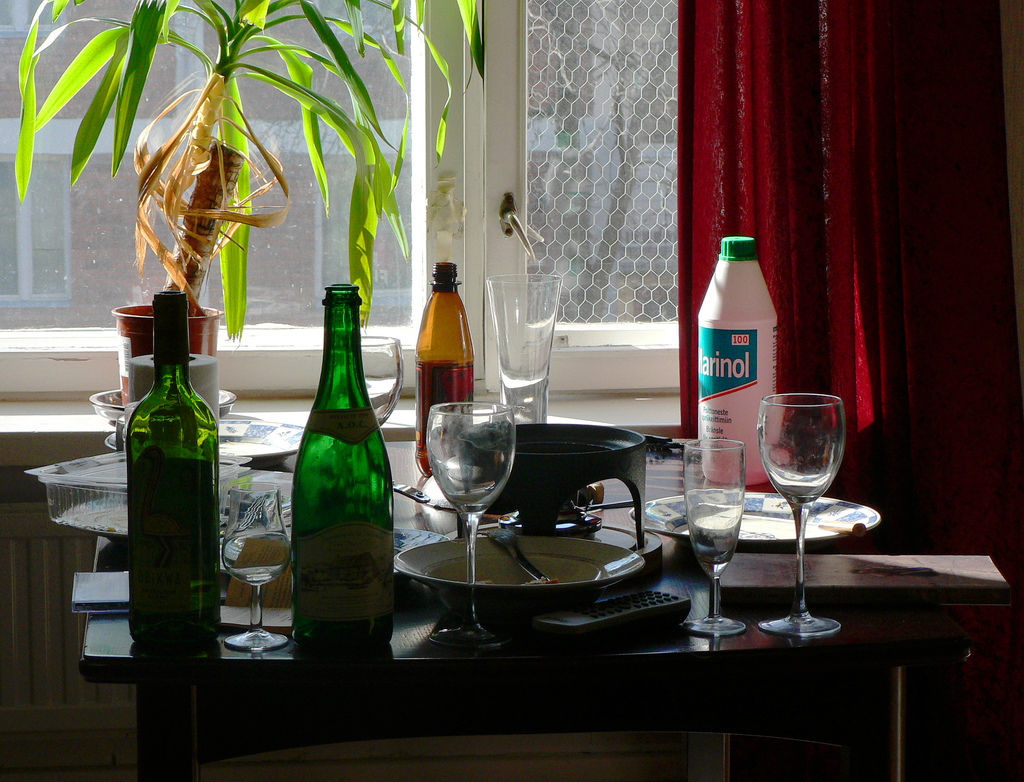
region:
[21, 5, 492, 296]
a plant in the window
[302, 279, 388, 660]
a green bottle on the table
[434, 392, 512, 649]
a wine glass on the table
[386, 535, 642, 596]
a white plate on the table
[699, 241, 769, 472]
a white bottle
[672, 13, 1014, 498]
red curtains on the window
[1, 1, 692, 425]
a window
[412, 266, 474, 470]
a brown bottle on the table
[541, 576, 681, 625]
a remote on the table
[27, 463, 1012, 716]
a table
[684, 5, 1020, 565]
Curtain panel on the window is red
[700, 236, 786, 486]
White and blue plastic bottle on table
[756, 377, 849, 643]
Empty wine glass on table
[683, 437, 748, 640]
Empty glass on table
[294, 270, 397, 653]
Empty green bottle on table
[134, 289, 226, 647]
Green bottle on edge of the table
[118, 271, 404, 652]
Two green bottles on edge of the table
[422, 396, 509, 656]
Empty glass on table next to green bottle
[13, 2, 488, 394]
Plant in pot has long green leaves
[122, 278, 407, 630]
two wine bottles sitting on the table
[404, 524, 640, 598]
a white plate sitting on the table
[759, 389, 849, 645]
a wine glass sitting on the table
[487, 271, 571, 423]
a tall glass sitting on the table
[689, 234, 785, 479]
a white bottle sitting on the table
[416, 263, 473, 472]
a brown bottle sitting on the table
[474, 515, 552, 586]
a fork laying on the white plate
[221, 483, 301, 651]
a glass sitting in between the bottles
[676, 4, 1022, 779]
the red curtain hanging by the window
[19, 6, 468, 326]
green tree in the pot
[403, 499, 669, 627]
empty plate with the fork on it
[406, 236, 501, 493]
brown liquor bottle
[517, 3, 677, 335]
chicken wire on the window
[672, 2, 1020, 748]
red curtains on the window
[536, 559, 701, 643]
remote on the table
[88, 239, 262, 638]
Bottle of wine on table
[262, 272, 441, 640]
Bottle of champagne on table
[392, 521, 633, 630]
Bowl on the table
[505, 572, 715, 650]
Remote control on table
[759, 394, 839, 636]
a wine glass on a table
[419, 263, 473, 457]
a brown bottle on the table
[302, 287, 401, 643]
a green bottle on the table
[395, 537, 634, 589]
a white plate on the table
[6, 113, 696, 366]
a window in the room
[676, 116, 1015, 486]
red curtains on the window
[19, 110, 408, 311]
a plant in the window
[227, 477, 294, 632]
a small wine glass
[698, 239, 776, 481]
a white bottle on the table